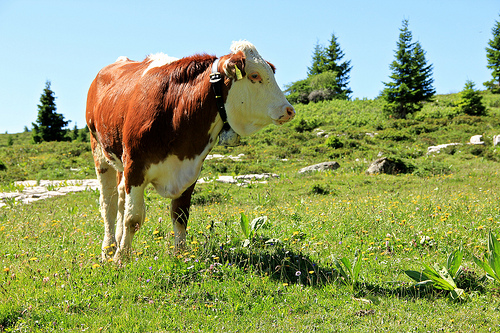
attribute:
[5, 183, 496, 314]
pasture — green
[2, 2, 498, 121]
sky — clear, blue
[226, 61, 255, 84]
tag — yellow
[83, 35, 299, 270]
cow — tagged, looking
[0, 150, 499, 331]
dandelions — yellow 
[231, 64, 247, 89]
tag — yellow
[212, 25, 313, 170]
face — white 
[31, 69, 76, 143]
tree —  evergreen,  small,  sturdy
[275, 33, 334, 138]
shrubbery — green , small 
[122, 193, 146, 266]
markings —  gorgeous,  white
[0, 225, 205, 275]
flowers — yellow